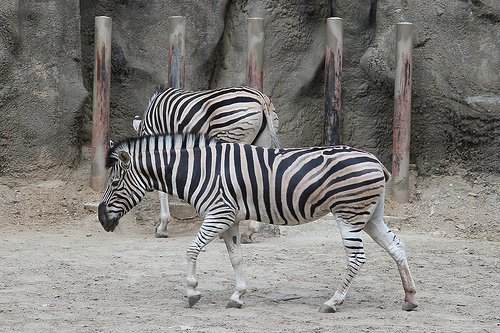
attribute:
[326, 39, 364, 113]
paint — missing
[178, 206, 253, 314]
legs — fully visible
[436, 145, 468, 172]
ground — dirt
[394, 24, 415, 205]
rusty pole — gray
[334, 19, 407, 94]
rocktip — pointy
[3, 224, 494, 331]
ground — brown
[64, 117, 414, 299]
zebra — fully visible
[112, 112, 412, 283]
zebra — walking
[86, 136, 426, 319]
zebra — striped, fully visible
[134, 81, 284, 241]
zebra — closest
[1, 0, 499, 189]
wall — rock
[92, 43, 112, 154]
marking — red, black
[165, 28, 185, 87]
marking — red, black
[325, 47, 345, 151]
marking — black, red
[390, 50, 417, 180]
marking — red, black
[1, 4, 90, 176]
boulder — gray, overlapping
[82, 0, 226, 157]
boulder — gray, overlapping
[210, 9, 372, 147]
boulder — gray, overlapping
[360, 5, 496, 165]
boulder — gray, overlapping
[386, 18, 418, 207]
pole — gray, rusty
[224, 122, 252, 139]
lines — wavy, thin